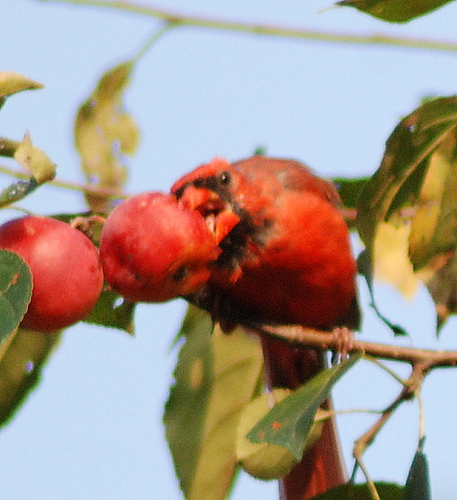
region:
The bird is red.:
[164, 139, 364, 336]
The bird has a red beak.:
[164, 158, 257, 259]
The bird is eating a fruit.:
[94, 146, 263, 303]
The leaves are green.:
[169, 323, 316, 480]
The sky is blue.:
[57, 364, 149, 478]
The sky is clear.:
[64, 359, 145, 462]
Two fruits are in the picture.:
[2, 186, 224, 327]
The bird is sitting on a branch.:
[162, 130, 378, 361]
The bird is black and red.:
[134, 146, 376, 354]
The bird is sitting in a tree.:
[90, 135, 399, 442]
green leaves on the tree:
[2, 52, 97, 206]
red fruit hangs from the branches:
[8, 189, 215, 344]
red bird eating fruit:
[146, 139, 388, 498]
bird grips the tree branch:
[232, 300, 393, 379]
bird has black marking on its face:
[145, 135, 299, 277]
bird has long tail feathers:
[250, 331, 383, 498]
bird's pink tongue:
[198, 212, 224, 247]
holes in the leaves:
[5, 145, 142, 397]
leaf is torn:
[205, 325, 391, 476]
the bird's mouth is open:
[138, 116, 437, 460]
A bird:
[192, 152, 383, 382]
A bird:
[160, 228, 269, 312]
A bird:
[247, 209, 314, 404]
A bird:
[230, 161, 327, 352]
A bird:
[221, 208, 296, 382]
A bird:
[259, 192, 360, 473]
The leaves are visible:
[164, 346, 288, 485]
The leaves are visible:
[91, 309, 328, 474]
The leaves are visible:
[187, 392, 299, 458]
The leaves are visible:
[166, 414, 267, 489]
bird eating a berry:
[168, 174, 253, 260]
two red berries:
[13, 217, 233, 320]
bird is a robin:
[233, 241, 389, 378]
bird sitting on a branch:
[265, 276, 389, 349]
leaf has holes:
[64, 57, 148, 198]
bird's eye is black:
[209, 148, 264, 196]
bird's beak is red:
[157, 168, 245, 243]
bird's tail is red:
[240, 338, 407, 498]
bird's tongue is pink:
[197, 211, 224, 237]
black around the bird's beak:
[161, 168, 251, 200]